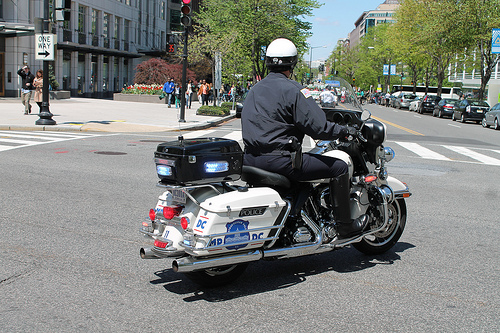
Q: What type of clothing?
A: Uniform.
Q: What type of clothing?
A: Uniform.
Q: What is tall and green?
A: Trees.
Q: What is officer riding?
A: Motorcycle.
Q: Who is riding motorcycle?
A: Officer.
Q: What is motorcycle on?
A: Road.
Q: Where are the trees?
A: Next to the road.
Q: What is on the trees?
A: Green leaves.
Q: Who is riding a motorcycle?
A: Police officer.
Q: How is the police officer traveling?
A: By motorcycle.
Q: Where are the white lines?
A: On the road.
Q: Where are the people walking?
A: On the sidewalk.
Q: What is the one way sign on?
A: Metal pole.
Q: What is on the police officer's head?
A: Helmet.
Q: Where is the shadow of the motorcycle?
A: Road.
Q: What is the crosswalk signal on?
A: Metal pole.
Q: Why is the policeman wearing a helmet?
A: Protect his head.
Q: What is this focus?
A: Policeman on bike.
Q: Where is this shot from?
A: Street.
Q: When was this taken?
A: Daytime.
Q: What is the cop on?
A: Motorcycle.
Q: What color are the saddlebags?
A: White.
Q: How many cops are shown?
A: 1.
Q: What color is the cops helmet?
A: White.